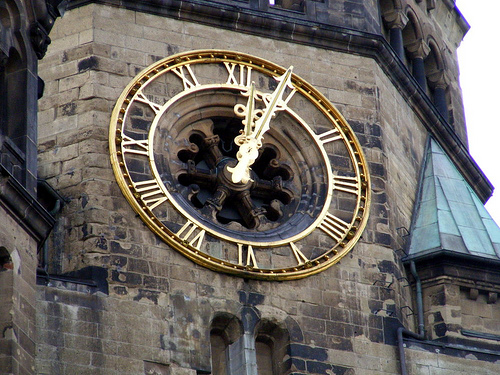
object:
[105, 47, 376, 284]
clock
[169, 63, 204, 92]
numeral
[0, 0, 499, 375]
building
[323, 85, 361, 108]
bricks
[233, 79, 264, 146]
hands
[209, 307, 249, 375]
arches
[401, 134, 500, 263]
roof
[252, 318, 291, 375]
window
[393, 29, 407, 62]
pillar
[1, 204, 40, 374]
wall